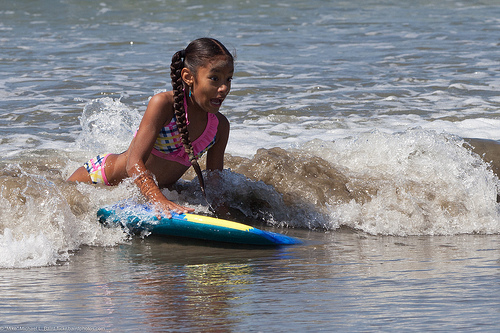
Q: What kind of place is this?
A: It is a sea.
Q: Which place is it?
A: It is a sea.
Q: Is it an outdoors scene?
A: Yes, it is outdoors.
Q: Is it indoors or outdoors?
A: It is outdoors.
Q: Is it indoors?
A: No, it is outdoors.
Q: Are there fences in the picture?
A: No, there are no fences.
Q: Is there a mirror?
A: No, there are no mirrors.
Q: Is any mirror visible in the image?
A: No, there are no mirrors.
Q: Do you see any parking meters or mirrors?
A: No, there are no mirrors or parking meters.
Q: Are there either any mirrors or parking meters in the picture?
A: No, there are no mirrors or parking meters.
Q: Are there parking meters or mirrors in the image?
A: No, there are no mirrors or parking meters.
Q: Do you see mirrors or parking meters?
A: No, there are no mirrors or parking meters.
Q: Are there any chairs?
A: No, there are no chairs.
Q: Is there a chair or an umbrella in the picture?
A: No, there are no chairs or umbrellas.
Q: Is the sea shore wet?
A: Yes, the sea shore is wet.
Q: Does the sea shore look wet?
A: Yes, the sea shore is wet.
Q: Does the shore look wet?
A: Yes, the shore is wet.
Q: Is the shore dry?
A: No, the shore is wet.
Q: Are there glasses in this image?
A: No, there are no glasses.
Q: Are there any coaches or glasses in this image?
A: No, there are no glasses or coaches.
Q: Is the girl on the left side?
A: Yes, the girl is on the left of the image.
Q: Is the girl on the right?
A: No, the girl is on the left of the image.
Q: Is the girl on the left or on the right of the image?
A: The girl is on the left of the image.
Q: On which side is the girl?
A: The girl is on the left of the image.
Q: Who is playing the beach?
A: The girl is playing the beach.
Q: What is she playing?
A: The girl is playing the beach.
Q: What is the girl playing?
A: The girl is playing the beach.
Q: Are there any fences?
A: No, there are no fences.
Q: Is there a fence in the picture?
A: No, there are no fences.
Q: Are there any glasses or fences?
A: No, there are no fences or glasses.